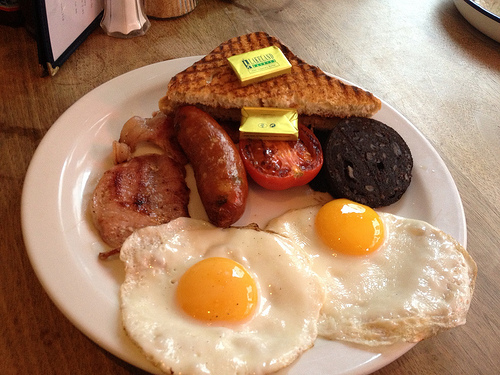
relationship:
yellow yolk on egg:
[316, 198, 387, 255] [275, 201, 475, 346]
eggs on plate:
[118, 198, 480, 373] [19, 55, 466, 375]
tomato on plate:
[236, 123, 317, 187] [19, 55, 473, 373]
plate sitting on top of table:
[19, 55, 473, 373] [4, 3, 496, 373]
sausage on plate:
[164, 103, 253, 223] [19, 55, 473, 373]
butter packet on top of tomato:
[228, 93, 316, 145] [237, 124, 325, 191]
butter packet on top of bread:
[223, 44, 294, 83] [278, 62, 382, 113]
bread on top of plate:
[158, 31, 381, 129] [19, 55, 473, 373]